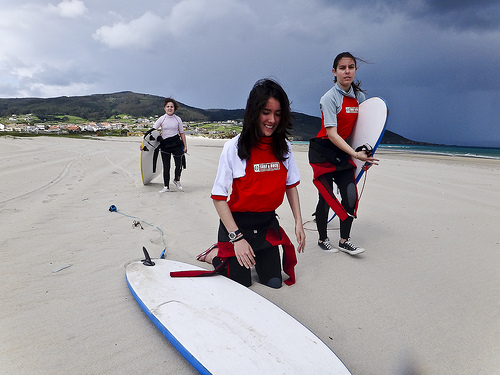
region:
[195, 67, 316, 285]
the girl is kneeling in the sand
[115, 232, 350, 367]
the surfboard is blue and white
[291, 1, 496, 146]
the sky is dark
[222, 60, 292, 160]
the girl's hair is black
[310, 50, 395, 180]
the girl is holding a surfboard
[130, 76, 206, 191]
the woman is watching the girls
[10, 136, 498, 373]
the sand is brown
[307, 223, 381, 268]
the girl's shoes are black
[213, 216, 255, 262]
the girl is wearing a watch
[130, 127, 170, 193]
the woman's surfboard is yellow and white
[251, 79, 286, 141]
A girl smiles big.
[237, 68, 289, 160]
The girl has long hair.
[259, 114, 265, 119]
The girl has a mole.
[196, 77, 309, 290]
A girl on her knees.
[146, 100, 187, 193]
An old lady walking.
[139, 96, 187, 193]
An old lady drags surfboard.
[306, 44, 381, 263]
The girl holds her board.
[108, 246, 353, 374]
The surf board lays on the beach.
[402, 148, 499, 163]
The waves come in.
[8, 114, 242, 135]
Houses on a hill.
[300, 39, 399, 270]
girl surfer on a windy day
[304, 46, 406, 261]
girl getting ready to surf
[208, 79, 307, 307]
girl kneeling on the sand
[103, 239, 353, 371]
white surf board with a blue edge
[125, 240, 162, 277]
small black fin on a surf board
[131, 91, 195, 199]
woman draggin a surf board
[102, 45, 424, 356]
trio of girls going surfing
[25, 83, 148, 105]
rocky black mountains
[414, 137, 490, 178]
ocean rolling into the beach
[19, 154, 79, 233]
drag marks in the sand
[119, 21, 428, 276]
three young girls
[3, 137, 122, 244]
tracks in the sand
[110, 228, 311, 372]
A white and blue surf board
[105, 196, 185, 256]
A strap on the surf board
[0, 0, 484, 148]
a dark, cloudy sky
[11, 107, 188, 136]
A small town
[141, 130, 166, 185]
a yellow and white surf board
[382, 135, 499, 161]
the ocean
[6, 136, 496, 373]
a beach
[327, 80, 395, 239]
a white and blue surf board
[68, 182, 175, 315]
the sand is white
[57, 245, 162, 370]
the sand is white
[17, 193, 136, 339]
the sand is white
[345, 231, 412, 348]
the sand is white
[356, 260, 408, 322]
the sand is white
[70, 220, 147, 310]
the sand is white